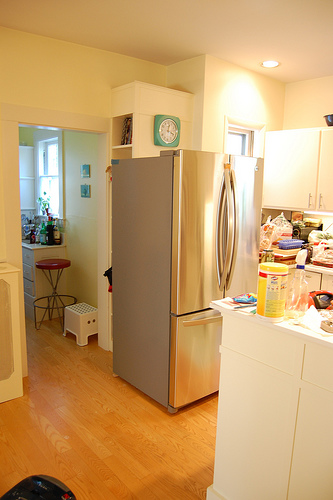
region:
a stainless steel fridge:
[113, 151, 247, 372]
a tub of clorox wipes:
[255, 265, 294, 319]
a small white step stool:
[50, 291, 99, 341]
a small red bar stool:
[35, 263, 73, 328]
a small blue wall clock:
[151, 111, 190, 154]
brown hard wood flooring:
[71, 413, 147, 485]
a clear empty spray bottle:
[291, 248, 313, 310]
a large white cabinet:
[253, 123, 331, 227]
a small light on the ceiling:
[252, 35, 284, 90]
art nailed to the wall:
[74, 154, 100, 212]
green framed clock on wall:
[149, 110, 186, 149]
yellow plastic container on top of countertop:
[249, 257, 291, 325]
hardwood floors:
[0, 299, 214, 497]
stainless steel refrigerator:
[106, 143, 266, 415]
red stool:
[27, 256, 83, 335]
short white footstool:
[55, 296, 102, 350]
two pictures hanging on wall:
[73, 157, 97, 201]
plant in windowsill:
[30, 185, 58, 219]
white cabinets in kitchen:
[265, 128, 331, 216]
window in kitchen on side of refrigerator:
[222, 124, 257, 158]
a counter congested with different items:
[268, 210, 332, 277]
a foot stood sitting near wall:
[56, 300, 110, 355]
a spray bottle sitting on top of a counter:
[287, 247, 312, 337]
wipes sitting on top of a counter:
[252, 262, 296, 355]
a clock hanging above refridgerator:
[148, 107, 188, 165]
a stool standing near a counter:
[35, 252, 69, 338]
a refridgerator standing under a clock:
[121, 150, 235, 407]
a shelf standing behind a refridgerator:
[102, 99, 152, 171]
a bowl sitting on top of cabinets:
[313, 103, 331, 117]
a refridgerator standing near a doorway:
[11, 154, 211, 380]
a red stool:
[33, 258, 76, 330]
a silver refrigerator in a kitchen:
[111, 150, 262, 414]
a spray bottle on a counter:
[284, 247, 311, 318]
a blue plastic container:
[276, 238, 303, 248]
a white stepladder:
[61, 303, 99, 344]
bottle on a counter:
[29, 217, 60, 246]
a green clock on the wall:
[153, 113, 181, 147]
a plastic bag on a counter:
[260, 216, 285, 253]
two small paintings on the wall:
[79, 162, 90, 198]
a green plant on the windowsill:
[36, 191, 51, 215]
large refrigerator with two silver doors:
[111, 149, 263, 409]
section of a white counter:
[205, 291, 331, 499]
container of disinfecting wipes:
[255, 260, 289, 322]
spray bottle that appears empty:
[285, 246, 309, 321]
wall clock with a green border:
[152, 113, 180, 146]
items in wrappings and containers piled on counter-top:
[260, 210, 332, 270]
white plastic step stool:
[59, 301, 96, 346]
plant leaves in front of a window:
[36, 141, 58, 216]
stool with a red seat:
[32, 257, 75, 332]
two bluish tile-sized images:
[79, 163, 89, 197]